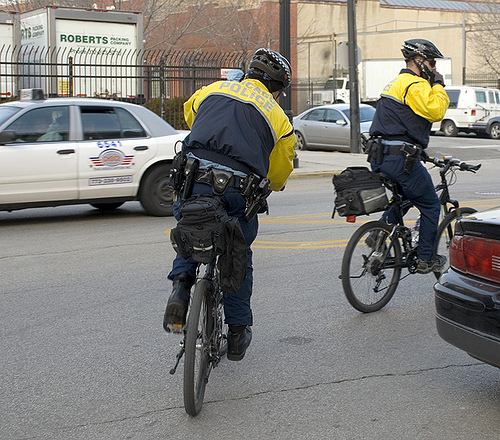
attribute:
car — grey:
[291, 102, 391, 154]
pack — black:
[329, 165, 391, 219]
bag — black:
[147, 188, 262, 274]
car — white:
[1, 85, 193, 222]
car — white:
[0, 87, 196, 204]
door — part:
[54, 19, 163, 106]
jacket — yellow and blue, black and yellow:
[182, 79, 297, 196]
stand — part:
[165, 367, 179, 378]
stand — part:
[335, 274, 368, 280]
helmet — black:
[241, 46, 296, 91]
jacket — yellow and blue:
[172, 77, 300, 203]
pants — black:
[367, 140, 446, 277]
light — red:
[429, 206, 498, 262]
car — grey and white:
[10, 22, 222, 183]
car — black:
[418, 220, 485, 357]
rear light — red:
[445, 228, 498, 291]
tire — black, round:
[340, 220, 403, 313]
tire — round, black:
[179, 273, 212, 420]